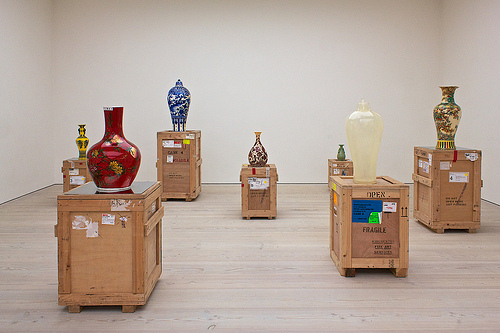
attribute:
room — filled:
[2, 2, 500, 332]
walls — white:
[2, 0, 499, 209]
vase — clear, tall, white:
[345, 97, 384, 186]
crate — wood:
[327, 171, 412, 279]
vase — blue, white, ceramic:
[165, 76, 192, 133]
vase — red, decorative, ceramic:
[84, 103, 143, 196]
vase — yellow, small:
[74, 123, 91, 163]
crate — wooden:
[156, 127, 203, 206]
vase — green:
[336, 141, 349, 162]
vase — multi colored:
[430, 83, 465, 151]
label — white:
[381, 199, 399, 215]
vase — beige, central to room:
[247, 128, 270, 169]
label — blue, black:
[351, 197, 383, 225]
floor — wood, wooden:
[0, 179, 499, 330]